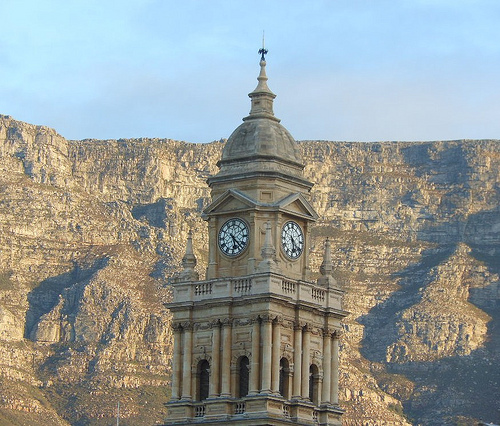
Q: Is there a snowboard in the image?
A: No, there are no snowboards.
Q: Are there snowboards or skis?
A: No, there are no snowboards or skis.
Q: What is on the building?
A: The dome is on the building.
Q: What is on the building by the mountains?
A: The dome is on the building.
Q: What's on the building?
A: The dome is on the building.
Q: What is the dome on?
A: The dome is on the building.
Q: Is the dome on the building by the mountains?
A: Yes, the dome is on the building.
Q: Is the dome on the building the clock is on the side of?
A: Yes, the dome is on the building.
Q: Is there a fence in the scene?
A: No, there are no fences.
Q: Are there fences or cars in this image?
A: No, there are no fences or cars.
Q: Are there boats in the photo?
A: No, there are no boats.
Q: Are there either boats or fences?
A: No, there are no boats or fences.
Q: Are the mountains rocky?
A: Yes, the mountains are rocky.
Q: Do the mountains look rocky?
A: Yes, the mountains are rocky.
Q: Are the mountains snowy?
A: No, the mountains are rocky.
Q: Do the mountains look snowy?
A: No, the mountains are rocky.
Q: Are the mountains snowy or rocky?
A: The mountains are rocky.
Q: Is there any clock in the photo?
A: Yes, there is a clock.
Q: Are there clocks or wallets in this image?
A: Yes, there is a clock.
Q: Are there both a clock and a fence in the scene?
A: No, there is a clock but no fences.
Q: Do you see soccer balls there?
A: No, there are no soccer balls.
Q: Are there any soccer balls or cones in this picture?
A: No, there are no soccer balls or cones.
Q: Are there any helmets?
A: No, there are no helmets.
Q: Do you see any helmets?
A: No, there are no helmets.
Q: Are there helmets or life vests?
A: No, there are no helmets or life vests.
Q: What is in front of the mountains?
A: The clocks are in front of the mountains.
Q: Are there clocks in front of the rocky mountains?
A: Yes, there are clocks in front of the mountains.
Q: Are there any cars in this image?
A: No, there are no cars.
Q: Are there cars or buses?
A: No, there are no cars or buses.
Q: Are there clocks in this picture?
A: Yes, there is a clock.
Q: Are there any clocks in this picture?
A: Yes, there is a clock.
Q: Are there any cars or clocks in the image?
A: Yes, there is a clock.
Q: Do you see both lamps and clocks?
A: No, there is a clock but no lamps.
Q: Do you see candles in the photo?
A: No, there are no candles.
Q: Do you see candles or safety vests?
A: No, there are no candles or safety vests.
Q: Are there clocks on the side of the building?
A: Yes, there is a clock on the side of the building.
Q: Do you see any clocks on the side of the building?
A: Yes, there is a clock on the side of the building.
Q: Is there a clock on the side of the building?
A: Yes, there is a clock on the side of the building.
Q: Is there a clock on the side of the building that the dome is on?
A: Yes, there is a clock on the side of the building.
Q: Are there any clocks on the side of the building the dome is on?
A: Yes, there is a clock on the side of the building.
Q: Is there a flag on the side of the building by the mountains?
A: No, there is a clock on the side of the building.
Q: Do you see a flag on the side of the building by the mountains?
A: No, there is a clock on the side of the building.